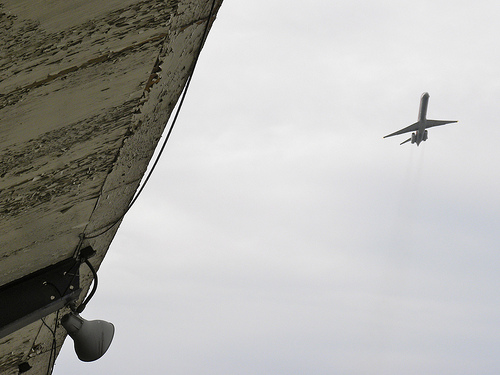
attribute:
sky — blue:
[219, 298, 393, 372]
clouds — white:
[296, 210, 347, 253]